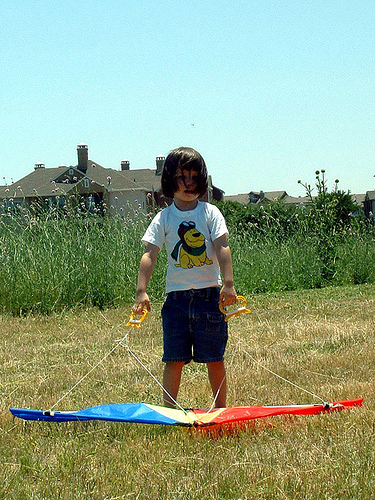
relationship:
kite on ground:
[14, 351, 363, 430] [270, 290, 362, 385]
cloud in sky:
[229, 148, 261, 187] [1, 2, 363, 146]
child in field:
[132, 145, 238, 408] [1, 281, 374, 493]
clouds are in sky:
[1, 93, 371, 214] [1, 0, 369, 211]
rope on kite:
[43, 325, 135, 417] [11, 394, 364, 428]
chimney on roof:
[75, 142, 89, 171] [0, 160, 170, 195]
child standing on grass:
[131, 145, 239, 411] [0, 281, 374, 499]